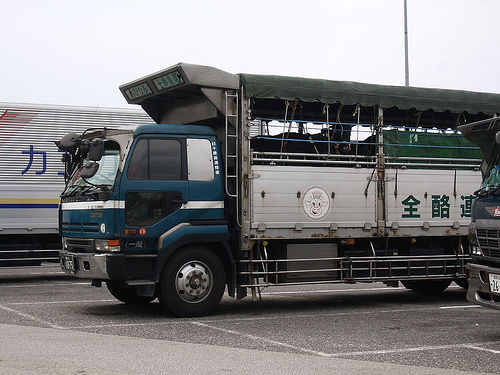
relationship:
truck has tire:
[106, 70, 419, 275] [158, 247, 228, 318]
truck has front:
[53, 59, 498, 322] [44, 117, 239, 309]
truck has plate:
[53, 59, 498, 322] [59, 253, 75, 271]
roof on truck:
[236, 70, 498, 115] [53, 59, 498, 322]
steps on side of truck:
[239, 235, 469, 286] [96, 44, 472, 211]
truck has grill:
[53, 59, 498, 322] [56, 204, 109, 278]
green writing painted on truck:
[407, 190, 477, 223] [53, 59, 498, 322]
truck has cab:
[53, 59, 498, 322] [59, 122, 232, 286]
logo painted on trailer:
[299, 186, 333, 221] [201, 68, 485, 285]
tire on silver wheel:
[158, 247, 228, 318] [175, 260, 214, 302]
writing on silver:
[17, 143, 51, 183] [6, 110, 136, 227]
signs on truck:
[117, 69, 189, 102] [53, 59, 498, 322]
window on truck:
[122, 137, 190, 188] [53, 59, 498, 322]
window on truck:
[61, 137, 135, 194] [53, 59, 498, 322]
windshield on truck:
[59, 138, 120, 201] [53, 59, 498, 322]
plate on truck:
[59, 253, 77, 271] [53, 59, 498, 322]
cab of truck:
[59, 122, 232, 286] [53, 59, 498, 322]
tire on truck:
[158, 247, 228, 317] [53, 59, 498, 322]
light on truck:
[82, 232, 113, 260] [47, 30, 484, 320]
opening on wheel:
[178, 269, 185, 279] [172, 259, 216, 301]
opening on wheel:
[177, 260, 211, 298] [157, 246, 229, 321]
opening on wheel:
[178, 264, 208, 302] [189, 260, 201, 273]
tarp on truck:
[234, 72, 499, 134] [53, 59, 498, 322]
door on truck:
[116, 137, 184, 234] [60, 80, 496, 314]